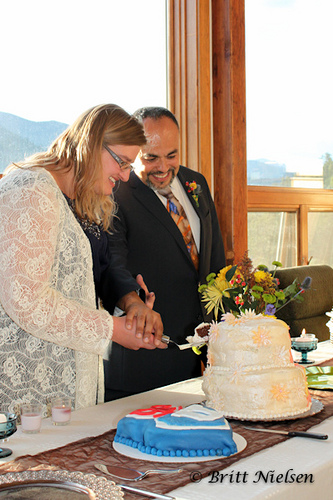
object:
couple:
[2, 104, 222, 414]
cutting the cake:
[116, 288, 312, 419]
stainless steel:
[0, 467, 124, 499]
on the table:
[2, 341, 333, 499]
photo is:
[2, 0, 333, 499]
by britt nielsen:
[191, 471, 315, 485]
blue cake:
[113, 405, 244, 463]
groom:
[133, 106, 226, 395]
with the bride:
[1, 104, 145, 414]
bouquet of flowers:
[196, 257, 311, 326]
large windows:
[2, 0, 333, 187]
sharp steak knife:
[242, 425, 326, 440]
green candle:
[291, 329, 318, 363]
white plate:
[113, 434, 249, 466]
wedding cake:
[203, 314, 311, 419]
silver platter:
[224, 393, 323, 423]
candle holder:
[292, 337, 317, 361]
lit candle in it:
[297, 327, 309, 341]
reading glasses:
[104, 141, 135, 171]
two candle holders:
[21, 405, 42, 435]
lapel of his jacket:
[183, 178, 204, 207]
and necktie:
[157, 187, 201, 267]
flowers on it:
[240, 309, 256, 320]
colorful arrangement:
[196, 249, 313, 313]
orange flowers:
[252, 329, 273, 347]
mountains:
[1, 95, 332, 188]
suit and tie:
[101, 165, 225, 400]